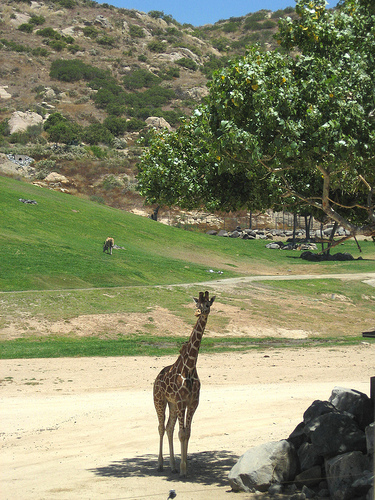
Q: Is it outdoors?
A: Yes, it is outdoors.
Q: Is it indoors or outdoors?
A: It is outdoors.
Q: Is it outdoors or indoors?
A: It is outdoors.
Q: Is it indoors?
A: No, it is outdoors.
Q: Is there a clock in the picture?
A: No, there are no clocks.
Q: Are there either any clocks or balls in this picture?
A: No, there are no clocks or balls.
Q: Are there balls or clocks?
A: No, there are no clocks or balls.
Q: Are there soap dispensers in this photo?
A: No, there are no soap dispensers.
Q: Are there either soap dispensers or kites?
A: No, there are no soap dispensers or kites.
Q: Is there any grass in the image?
A: Yes, there is grass.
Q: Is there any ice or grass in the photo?
A: Yes, there is grass.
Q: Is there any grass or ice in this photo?
A: Yes, there is grass.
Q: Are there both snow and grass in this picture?
A: No, there is grass but no snow.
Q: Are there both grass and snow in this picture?
A: No, there is grass but no snow.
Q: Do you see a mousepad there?
A: No, there are no mouse pads.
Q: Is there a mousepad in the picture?
A: No, there are no mouse pads.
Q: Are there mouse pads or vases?
A: No, there are no mouse pads or vases.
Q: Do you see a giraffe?
A: Yes, there is a giraffe.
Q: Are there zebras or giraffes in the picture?
A: Yes, there is a giraffe.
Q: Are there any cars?
A: No, there are no cars.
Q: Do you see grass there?
A: Yes, there is grass.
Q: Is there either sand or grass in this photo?
A: Yes, there is grass.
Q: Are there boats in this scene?
A: No, there are no boats.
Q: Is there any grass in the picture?
A: Yes, there is grass.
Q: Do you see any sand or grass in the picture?
A: Yes, there is grass.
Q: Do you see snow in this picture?
A: No, there is no snow.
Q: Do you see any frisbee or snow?
A: No, there are no snow or frisbees.